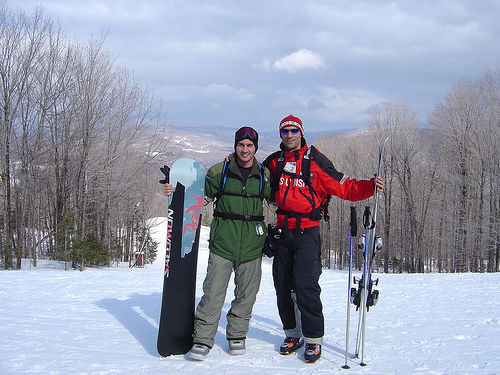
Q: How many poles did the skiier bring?
A: Two.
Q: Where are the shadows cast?
A: Towards the top left of the photo.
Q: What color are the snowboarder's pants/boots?
A: Grey.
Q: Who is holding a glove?
A: The snowboarder.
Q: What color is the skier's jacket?
A: Red.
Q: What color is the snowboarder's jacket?
A: Green.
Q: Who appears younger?
A: The man in green.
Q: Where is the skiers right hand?
A: On the snowboarder's back.